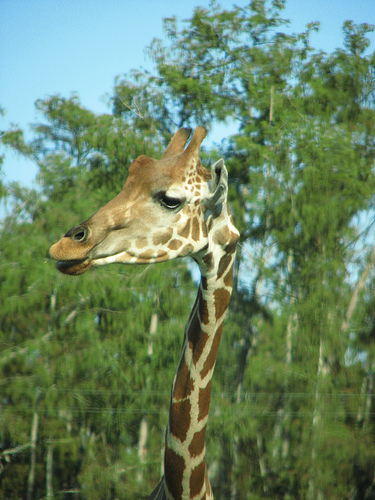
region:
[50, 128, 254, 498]
giraffe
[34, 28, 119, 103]
white clouds in blue sky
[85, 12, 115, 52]
white clouds in blue sky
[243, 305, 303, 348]
green leaves in brown tree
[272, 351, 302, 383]
green leaves in brown tree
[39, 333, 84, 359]
green leaves in brown tree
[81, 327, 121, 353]
green leaves in brown tree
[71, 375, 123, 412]
green leaves in brown tree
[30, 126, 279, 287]
head of a giraffe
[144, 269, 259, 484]
neck of a giraffe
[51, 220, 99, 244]
nose of a giraffe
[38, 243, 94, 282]
mouth of a giraffe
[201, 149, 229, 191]
ear of a giraffe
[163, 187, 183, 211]
eye of a giraffe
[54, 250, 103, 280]
jaw of a giraffe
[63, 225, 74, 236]
nose of a giraffe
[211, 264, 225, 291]
skin of a giraffe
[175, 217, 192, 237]
The spot is brown.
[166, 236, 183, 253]
The spot is brown.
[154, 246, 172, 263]
The spot is brown.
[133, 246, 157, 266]
The spot is brown.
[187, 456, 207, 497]
The spot is brown.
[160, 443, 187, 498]
The spot is brown.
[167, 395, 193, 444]
The spot is brown.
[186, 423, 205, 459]
The spot is brown.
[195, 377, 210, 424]
The spot is brown.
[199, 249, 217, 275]
The spot is brown.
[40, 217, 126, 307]
the mouth of a giraffe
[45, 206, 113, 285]
the nose of a giraffe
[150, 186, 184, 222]
the eye of a giraffe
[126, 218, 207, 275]
the jaw of a giraffe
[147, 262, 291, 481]
the neck of a giraffe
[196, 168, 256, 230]
the ear of a giraffe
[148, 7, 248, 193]
the horns of a giraffe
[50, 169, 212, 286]
the face of a giraffe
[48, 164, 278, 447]
a brown spotted giraffe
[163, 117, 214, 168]
two nubs sticking up from giraffe's head, horns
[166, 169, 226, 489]
square, rectangular and oblong patches of brown on tan making up giraffe's unique pattern of color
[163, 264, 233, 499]
brown on tan hide covering of giraffe's neck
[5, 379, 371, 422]
wire fence in background behind giraffe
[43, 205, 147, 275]
giraffe mouth with two holes like a nose would have on upperside of mouth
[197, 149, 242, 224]
giraffe ear located near back of head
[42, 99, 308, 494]
giraffe shown from neck up with head pointed toward the left side of photo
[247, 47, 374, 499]
tall trees with foilage in background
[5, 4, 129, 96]
clear blue sky without clouds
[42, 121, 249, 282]
giraffe looking down from way up high